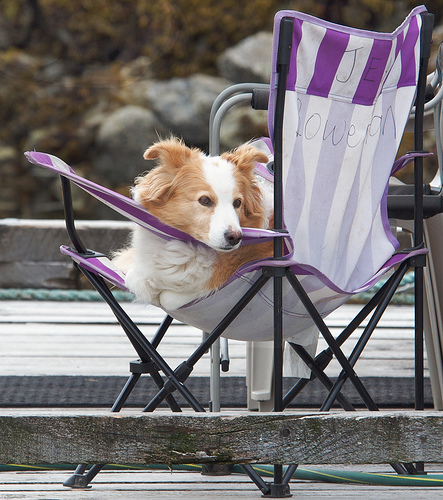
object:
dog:
[108, 133, 289, 303]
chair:
[24, 3, 430, 414]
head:
[143, 133, 269, 252]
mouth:
[218, 222, 244, 253]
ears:
[143, 135, 269, 173]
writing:
[294, 31, 415, 150]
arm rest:
[21, 150, 287, 255]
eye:
[198, 193, 213, 207]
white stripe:
[199, 151, 241, 237]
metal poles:
[63, 283, 442, 498]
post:
[1, 410, 443, 459]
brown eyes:
[198, 194, 242, 209]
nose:
[223, 221, 243, 245]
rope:
[1, 281, 422, 305]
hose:
[2, 460, 438, 491]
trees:
[2, 3, 443, 193]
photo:
[0, 2, 443, 498]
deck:
[0, 303, 441, 500]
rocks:
[91, 23, 289, 149]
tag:
[281, 330, 319, 378]